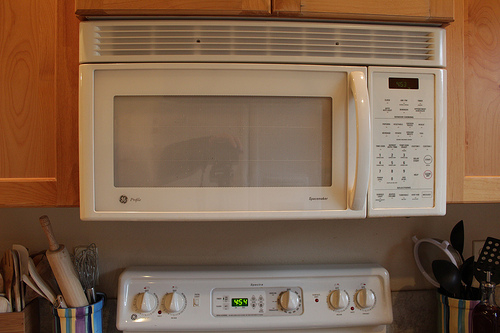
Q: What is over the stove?
A: White microwave.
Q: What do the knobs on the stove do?
A: Turn the burners on and off.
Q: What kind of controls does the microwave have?
A: Push button.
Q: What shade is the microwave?
A: White.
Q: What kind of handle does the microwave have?
A: Long and white.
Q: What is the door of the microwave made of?
A: Glass.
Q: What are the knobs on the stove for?
A: Controls.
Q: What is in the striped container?
A: Kitchen utensils.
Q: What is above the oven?
A: A microwave.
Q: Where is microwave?
A: On the wall.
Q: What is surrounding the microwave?
A: Cabinets.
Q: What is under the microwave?
A: Stove.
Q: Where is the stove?
A: Under the microwave.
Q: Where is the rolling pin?
A: To the left of the stove.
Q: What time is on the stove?
A: 4:54.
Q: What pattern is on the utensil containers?
A: Stripes.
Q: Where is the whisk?
A: On the left of the stove.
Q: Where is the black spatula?
A: To the right of the stove.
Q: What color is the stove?
A: White.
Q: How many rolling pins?
A: One.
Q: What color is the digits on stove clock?
A: Green.